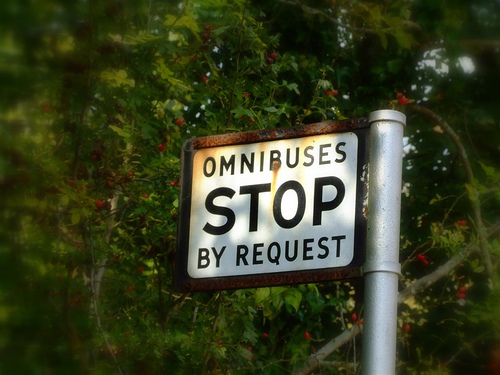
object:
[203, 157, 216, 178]
letters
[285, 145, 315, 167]
letters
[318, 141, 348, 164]
letters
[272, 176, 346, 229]
letters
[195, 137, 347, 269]
word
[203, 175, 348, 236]
stop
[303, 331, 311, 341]
berry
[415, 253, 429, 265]
berry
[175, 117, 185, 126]
berry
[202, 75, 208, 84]
berry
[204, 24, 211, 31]
berry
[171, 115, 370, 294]
rust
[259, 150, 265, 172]
letter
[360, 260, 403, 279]
bracket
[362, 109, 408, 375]
pole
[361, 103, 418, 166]
wall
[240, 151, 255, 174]
n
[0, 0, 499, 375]
leaf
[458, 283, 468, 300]
red berry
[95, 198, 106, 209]
red berry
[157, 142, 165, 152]
red berry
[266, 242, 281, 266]
letter q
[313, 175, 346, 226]
p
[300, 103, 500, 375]
branch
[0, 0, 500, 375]
tree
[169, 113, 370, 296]
sign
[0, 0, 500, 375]
green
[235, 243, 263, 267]
letters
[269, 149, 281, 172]
letter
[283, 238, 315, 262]
letters ue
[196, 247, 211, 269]
letter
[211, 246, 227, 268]
letter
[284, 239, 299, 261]
letter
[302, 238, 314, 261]
letter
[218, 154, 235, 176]
letter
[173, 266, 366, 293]
rust spot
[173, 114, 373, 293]
frame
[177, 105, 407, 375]
sign post